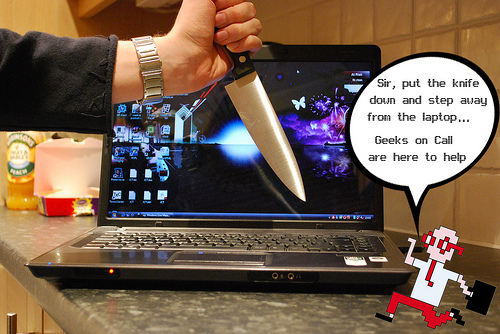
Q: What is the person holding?
A: A knife.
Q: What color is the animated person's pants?
A: Red.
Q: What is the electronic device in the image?
A: Laptop.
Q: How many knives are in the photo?
A: One.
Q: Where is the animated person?
A: Bottom right.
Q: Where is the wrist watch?
A: On the person.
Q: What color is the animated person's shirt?
A: White.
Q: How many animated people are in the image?
A: One.